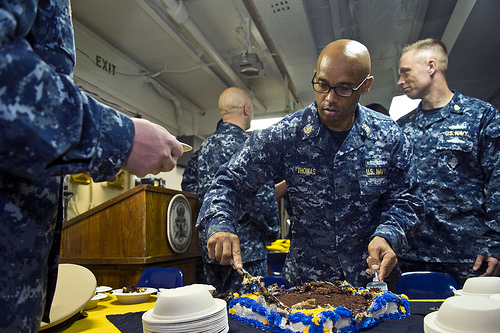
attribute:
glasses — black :
[310, 69, 368, 99]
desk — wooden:
[59, 189, 209, 291]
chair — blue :
[131, 251, 199, 303]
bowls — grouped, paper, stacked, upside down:
[142, 283, 236, 331]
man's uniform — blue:
[236, 122, 411, 262]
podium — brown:
[49, 166, 211, 307]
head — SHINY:
[293, 22, 393, 142]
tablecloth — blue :
[85, 302, 140, 332]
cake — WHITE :
[217, 269, 409, 331]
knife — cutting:
[229, 253, 289, 310]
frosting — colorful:
[265, 270, 372, 310]